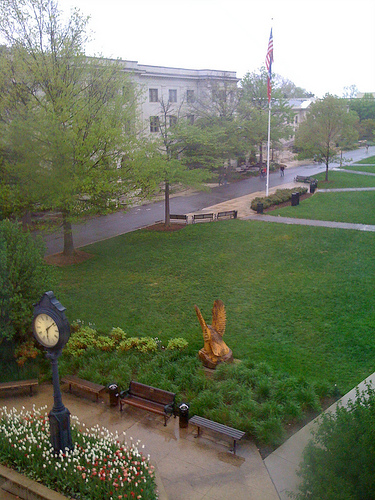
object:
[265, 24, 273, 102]
flag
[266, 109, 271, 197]
pole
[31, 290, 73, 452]
clock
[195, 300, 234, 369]
golden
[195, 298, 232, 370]
statue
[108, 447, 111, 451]
flowers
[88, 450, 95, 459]
white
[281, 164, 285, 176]
people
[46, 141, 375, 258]
road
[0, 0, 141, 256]
trees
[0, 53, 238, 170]
building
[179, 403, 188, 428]
trash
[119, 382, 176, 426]
bench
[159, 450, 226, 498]
cement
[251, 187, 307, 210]
bushes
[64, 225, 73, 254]
wood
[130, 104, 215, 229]
tree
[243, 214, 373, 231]
walkway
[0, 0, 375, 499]
campus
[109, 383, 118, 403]
ashtray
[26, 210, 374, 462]
grass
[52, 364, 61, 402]
black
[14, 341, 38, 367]
landscaping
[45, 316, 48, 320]
numerals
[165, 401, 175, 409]
arms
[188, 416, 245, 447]
benches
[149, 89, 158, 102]
windows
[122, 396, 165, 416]
brown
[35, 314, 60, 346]
white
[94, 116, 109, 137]
green